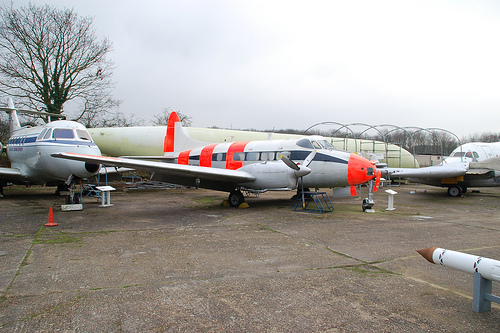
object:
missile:
[416, 246, 500, 278]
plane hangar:
[303, 120, 464, 167]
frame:
[302, 121, 460, 167]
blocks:
[218, 198, 250, 209]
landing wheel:
[226, 190, 244, 207]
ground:
[0, 169, 500, 331]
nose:
[348, 154, 383, 196]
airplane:
[372, 139, 495, 197]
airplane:
[49, 109, 390, 213]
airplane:
[0, 97, 140, 209]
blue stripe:
[3, 135, 36, 143]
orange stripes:
[179, 140, 249, 169]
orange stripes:
[163, 111, 178, 151]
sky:
[75, 0, 498, 129]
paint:
[348, 149, 379, 188]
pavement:
[0, 180, 497, 332]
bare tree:
[0, 0, 115, 122]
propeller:
[277, 150, 323, 209]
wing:
[50, 150, 256, 184]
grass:
[28, 226, 76, 247]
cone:
[45, 207, 58, 227]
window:
[220, 153, 227, 161]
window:
[234, 152, 246, 160]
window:
[244, 151, 258, 160]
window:
[260, 150, 276, 159]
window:
[277, 150, 289, 158]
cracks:
[0, 228, 53, 308]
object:
[298, 116, 459, 154]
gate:
[11, 110, 470, 183]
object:
[412, 234, 498, 322]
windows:
[212, 153, 217, 160]